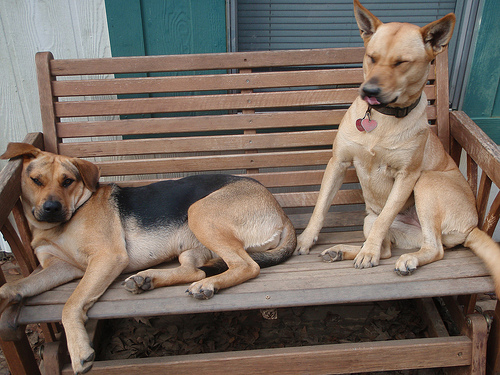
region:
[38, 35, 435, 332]
two dogs on bench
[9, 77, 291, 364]
this dog is laying down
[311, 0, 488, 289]
this dog is sitting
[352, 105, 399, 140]
the tags are heart shaped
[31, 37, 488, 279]
the bench is wood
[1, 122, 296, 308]
the dog is tan and black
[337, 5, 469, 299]
this dog is sneezing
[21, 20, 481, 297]
the dogs are together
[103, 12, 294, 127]
green wood behind bench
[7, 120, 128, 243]
the dog's ear is on the armrest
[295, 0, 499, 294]
Brown dog sitting on the bench.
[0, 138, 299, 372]
Black and tan dog laying on the bench.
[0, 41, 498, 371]
Brown wooden bench in front of house.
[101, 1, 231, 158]
aqua shutter on the house.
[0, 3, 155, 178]
Gray wood on the side of the house.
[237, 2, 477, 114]
Gray blinds in the window.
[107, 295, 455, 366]
Brown leaves on the bench.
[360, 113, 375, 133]
Ping heart tag on the dog.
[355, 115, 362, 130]
Red tag on the dog.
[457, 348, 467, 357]
Screw in the wood on the bench.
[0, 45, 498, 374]
wooden bench with two dogs on it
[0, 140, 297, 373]
dog laying on a bench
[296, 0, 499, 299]
dog sitting on a bench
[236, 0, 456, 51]
window behind a bench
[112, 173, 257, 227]
black spot of a dog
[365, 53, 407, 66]
closed eyes of a dog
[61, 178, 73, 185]
open eye of a dog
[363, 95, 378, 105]
tongue of a dog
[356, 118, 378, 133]
pink and red dog tags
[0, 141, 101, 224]
head of a dog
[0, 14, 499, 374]
two German Shepherds on a wood bench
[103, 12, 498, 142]
teal blue window frame behind wood bench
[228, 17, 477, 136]
teal blue window blinds behind wood bench and dog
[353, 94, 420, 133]
dog collar with two red tags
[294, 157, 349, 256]
right front leg of sitting dog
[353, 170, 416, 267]
left front leg of sitting dog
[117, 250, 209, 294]
right rear leg of dog that is laying down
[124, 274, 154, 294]
four black paw pads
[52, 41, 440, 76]
top slat of wood bench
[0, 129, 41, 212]
right ear of dog on arm of bench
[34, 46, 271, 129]
Brown wooden park bench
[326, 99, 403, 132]
Two tags on dog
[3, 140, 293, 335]
lazy dog laying down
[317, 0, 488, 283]
Dog with eyes closed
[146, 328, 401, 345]
Dead leaves under bench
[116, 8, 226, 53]
Green painted windows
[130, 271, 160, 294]
paw pads of dog feet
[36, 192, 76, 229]
Black nose of dog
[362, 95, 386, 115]
Dog with tongue out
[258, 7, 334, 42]
Mini blinds on window